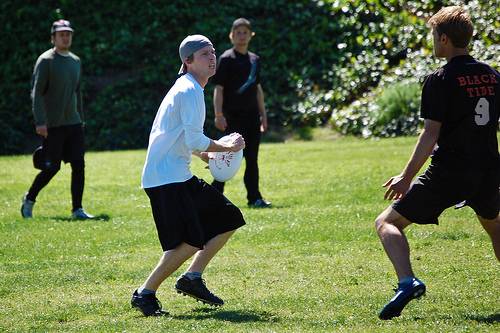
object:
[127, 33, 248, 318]
man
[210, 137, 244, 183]
ball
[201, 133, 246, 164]
hands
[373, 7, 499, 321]
opponent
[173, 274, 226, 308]
sneaker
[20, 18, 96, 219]
man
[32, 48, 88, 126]
shirt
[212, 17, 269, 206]
spectator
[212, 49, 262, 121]
shirt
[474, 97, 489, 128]
number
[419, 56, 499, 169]
shirt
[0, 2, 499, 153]
trees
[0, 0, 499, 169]
background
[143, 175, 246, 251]
shorts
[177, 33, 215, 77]
hat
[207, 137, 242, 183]
frisbee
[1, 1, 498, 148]
vegetation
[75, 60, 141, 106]
rocks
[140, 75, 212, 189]
shirt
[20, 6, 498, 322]
men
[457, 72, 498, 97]
lettering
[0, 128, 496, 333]
field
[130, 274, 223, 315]
cleats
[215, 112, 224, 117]
armband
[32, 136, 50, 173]
cap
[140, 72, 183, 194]
backside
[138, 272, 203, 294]
socks